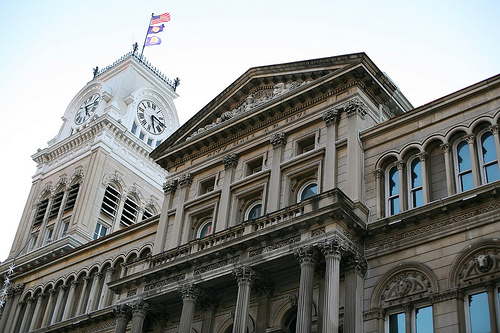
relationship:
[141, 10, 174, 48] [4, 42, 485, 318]
flag on building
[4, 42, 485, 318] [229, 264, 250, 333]
building has pillar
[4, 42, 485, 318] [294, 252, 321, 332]
building has pillar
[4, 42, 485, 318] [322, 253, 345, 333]
building has pillar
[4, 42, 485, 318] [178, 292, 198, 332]
building has pillar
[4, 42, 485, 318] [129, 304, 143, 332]
building has pillar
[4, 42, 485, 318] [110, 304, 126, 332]
building has pillar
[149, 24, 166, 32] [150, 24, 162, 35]
flag has circle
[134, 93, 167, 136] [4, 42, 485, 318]
clock on building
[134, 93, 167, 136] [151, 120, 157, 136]
clock has hand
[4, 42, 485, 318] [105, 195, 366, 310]
building has balcony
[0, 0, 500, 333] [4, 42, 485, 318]
tower beside building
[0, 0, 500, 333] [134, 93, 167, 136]
tower has clock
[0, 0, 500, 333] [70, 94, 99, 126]
tower has clock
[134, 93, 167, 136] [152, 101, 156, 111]
clock has numeral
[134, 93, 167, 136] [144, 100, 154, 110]
clock has numeral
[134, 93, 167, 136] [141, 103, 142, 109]
clock has numeral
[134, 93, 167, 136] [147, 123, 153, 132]
clock has numeral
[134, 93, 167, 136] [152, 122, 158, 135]
clock has numeral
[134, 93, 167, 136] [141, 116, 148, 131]
clock has numeral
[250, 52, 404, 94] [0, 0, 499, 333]
roof on building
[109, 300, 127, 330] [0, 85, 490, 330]
pillar on building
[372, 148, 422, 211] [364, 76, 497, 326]
window on building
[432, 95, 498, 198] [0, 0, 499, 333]
window on building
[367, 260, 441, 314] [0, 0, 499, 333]
decorative pattern on building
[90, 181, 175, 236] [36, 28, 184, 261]
window on building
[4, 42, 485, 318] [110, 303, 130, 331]
building has column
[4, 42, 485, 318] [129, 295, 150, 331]
building has column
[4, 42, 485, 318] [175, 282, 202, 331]
building has column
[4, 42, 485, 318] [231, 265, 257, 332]
building has column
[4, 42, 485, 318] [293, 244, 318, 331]
building has column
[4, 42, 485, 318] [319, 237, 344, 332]
building has column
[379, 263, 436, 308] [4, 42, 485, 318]
gargoyles on building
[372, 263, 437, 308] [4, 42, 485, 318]
gargoyles on building